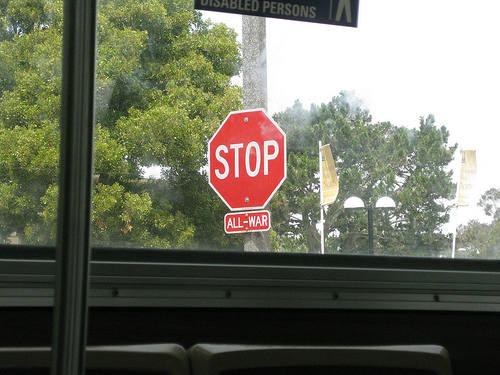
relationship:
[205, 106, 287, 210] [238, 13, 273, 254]
stop sign mounted on pole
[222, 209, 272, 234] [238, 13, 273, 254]
sign mounted on pole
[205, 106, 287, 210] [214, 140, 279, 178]
stop sign says stop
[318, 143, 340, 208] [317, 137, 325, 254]
flag hanging on pole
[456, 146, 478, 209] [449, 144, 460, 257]
flag hanging on pole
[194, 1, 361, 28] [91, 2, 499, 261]
sign hanging on window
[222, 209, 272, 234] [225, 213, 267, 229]
sign reads all war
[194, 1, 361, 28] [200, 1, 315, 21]
sign has text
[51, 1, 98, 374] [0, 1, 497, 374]
rail inside of vehicle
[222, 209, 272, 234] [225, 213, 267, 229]
sign says all war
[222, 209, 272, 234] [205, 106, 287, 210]
sign below stop sign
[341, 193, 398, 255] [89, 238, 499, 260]
street lamp on side of road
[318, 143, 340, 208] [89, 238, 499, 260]
flag on side of road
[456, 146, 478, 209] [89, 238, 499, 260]
flag on side of road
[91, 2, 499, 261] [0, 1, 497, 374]
window inside of vehicle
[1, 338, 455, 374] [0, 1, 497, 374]
chair backs inside of vehicle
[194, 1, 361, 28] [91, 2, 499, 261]
sign stuck on window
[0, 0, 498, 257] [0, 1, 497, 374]
trees outside of vehicle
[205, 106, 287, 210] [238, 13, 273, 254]
stop sign posted on pole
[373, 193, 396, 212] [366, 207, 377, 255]
globe on top of post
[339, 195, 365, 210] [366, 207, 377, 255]
globe on top of post